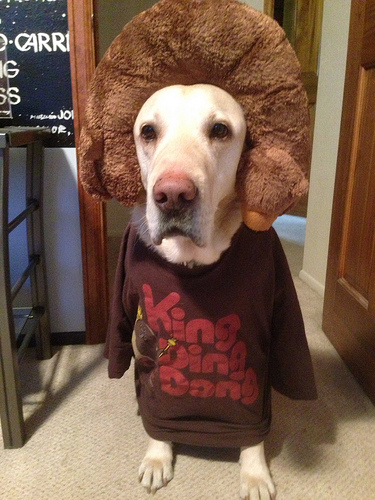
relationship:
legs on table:
[25, 145, 56, 362] [1, 123, 57, 452]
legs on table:
[2, 153, 27, 451] [1, 123, 57, 452]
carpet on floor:
[3, 202, 375, 496] [2, 205, 374, 498]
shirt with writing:
[97, 207, 324, 458] [137, 282, 261, 409]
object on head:
[74, 2, 312, 239] [125, 74, 245, 263]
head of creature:
[125, 74, 245, 263] [128, 82, 277, 499]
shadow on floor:
[261, 343, 371, 477] [2, 205, 374, 498]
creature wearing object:
[128, 82, 277, 499] [74, 2, 312, 239]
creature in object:
[128, 82, 277, 499] [74, 2, 312, 239]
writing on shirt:
[137, 282, 261, 409] [97, 207, 324, 458]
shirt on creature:
[97, 207, 324, 458] [128, 82, 277, 499]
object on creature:
[74, 2, 312, 239] [128, 82, 277, 499]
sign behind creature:
[1, 1, 83, 152] [128, 82, 277, 499]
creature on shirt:
[128, 308, 159, 407] [97, 207, 324, 458]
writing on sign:
[1, 30, 74, 137] [1, 1, 83, 152]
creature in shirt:
[128, 82, 277, 499] [97, 207, 324, 458]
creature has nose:
[128, 82, 277, 499] [150, 167, 200, 212]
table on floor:
[1, 123, 57, 452] [2, 205, 374, 498]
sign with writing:
[1, 1, 83, 152] [1, 30, 74, 137]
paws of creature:
[233, 454, 280, 499] [128, 82, 277, 499]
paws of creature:
[134, 441, 177, 495] [128, 82, 277, 499]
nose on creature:
[150, 167, 200, 212] [128, 82, 277, 499]